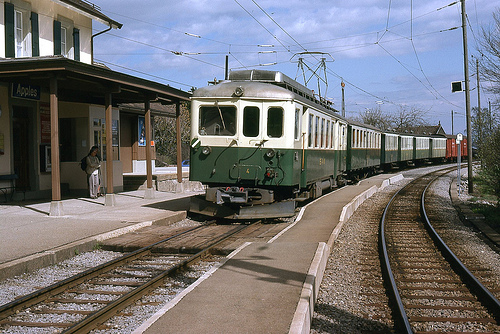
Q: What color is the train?
A: Green, white, and red.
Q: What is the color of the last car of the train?
A: Red.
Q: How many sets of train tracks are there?
A: Two.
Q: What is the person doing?
A: Waiting at the station.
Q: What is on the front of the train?
A: A cow catcher.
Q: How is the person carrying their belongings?
A: In a backpack.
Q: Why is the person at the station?
A: To ride on the train.